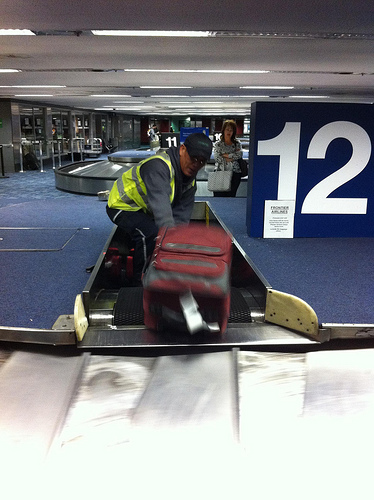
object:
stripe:
[164, 243, 221, 253]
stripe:
[155, 272, 217, 285]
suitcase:
[102, 239, 137, 284]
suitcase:
[25, 150, 41, 170]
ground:
[337, 144, 346, 161]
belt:
[1, 346, 372, 474]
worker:
[105, 133, 213, 286]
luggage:
[140, 226, 232, 343]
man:
[105, 133, 214, 288]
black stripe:
[160, 258, 217, 269]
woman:
[212, 123, 247, 196]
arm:
[227, 150, 243, 161]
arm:
[213, 142, 225, 163]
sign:
[250, 99, 372, 238]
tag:
[179, 294, 221, 335]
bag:
[207, 163, 233, 192]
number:
[257, 119, 373, 219]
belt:
[115, 287, 141, 323]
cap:
[184, 132, 213, 161]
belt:
[63, 161, 117, 175]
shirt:
[140, 145, 198, 234]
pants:
[105, 204, 158, 279]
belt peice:
[63, 139, 134, 180]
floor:
[0, 182, 89, 221]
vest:
[106, 150, 176, 214]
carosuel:
[53, 153, 223, 197]